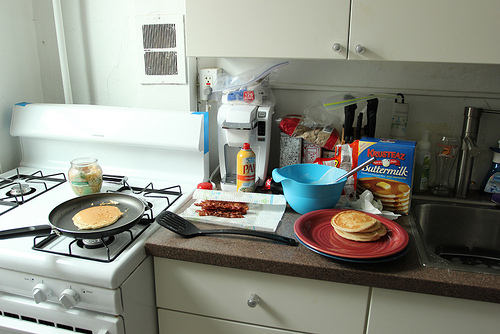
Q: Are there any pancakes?
A: Yes, there are pancakes.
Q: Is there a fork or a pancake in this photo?
A: Yes, there are pancakes.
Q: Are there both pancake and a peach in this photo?
A: No, there are pancakes but no peaches.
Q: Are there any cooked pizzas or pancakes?
A: Yes, there are cooked pancakes.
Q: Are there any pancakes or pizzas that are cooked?
A: Yes, the pancakes are cooked.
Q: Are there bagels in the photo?
A: No, there are no bagels.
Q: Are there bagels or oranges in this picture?
A: No, there are no bagels or oranges.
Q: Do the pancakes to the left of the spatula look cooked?
A: Yes, the pancakes are cooked.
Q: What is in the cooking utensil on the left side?
A: The pancakes are in the skillet.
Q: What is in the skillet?
A: The pancakes are in the skillet.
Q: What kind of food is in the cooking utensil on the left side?
A: The food is pancakes.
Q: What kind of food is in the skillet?
A: The food is pancakes.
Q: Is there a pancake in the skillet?
A: Yes, there are pancakes in the skillet.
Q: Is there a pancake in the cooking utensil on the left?
A: Yes, there are pancakes in the skillet.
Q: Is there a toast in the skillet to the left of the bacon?
A: No, there are pancakes in the skillet.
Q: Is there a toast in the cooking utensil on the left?
A: No, there are pancakes in the skillet.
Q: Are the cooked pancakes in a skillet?
A: Yes, the pancakes are in a skillet.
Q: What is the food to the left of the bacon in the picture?
A: The food is pancakes.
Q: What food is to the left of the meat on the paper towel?
A: The food is pancakes.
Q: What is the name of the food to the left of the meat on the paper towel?
A: The food is pancakes.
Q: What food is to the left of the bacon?
A: The food is pancakes.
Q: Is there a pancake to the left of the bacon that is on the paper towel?
A: Yes, there are pancakes to the left of the bacon.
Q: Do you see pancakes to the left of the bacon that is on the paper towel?
A: Yes, there are pancakes to the left of the bacon.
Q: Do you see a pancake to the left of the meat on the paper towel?
A: Yes, there are pancakes to the left of the bacon.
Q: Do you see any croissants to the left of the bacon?
A: No, there are pancakes to the left of the bacon.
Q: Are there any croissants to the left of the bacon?
A: No, there are pancakes to the left of the bacon.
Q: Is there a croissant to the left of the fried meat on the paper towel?
A: No, there are pancakes to the left of the bacon.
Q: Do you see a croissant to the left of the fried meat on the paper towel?
A: No, there are pancakes to the left of the bacon.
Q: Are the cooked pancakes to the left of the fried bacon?
A: Yes, the pancakes are to the left of the bacon.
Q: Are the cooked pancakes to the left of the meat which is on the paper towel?
A: Yes, the pancakes are to the left of the bacon.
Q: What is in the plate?
A: The pancakes are in the plate.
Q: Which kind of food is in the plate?
A: The food is pancakes.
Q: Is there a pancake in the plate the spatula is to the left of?
A: Yes, there are pancakes in the plate.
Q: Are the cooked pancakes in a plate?
A: Yes, the pancakes are in a plate.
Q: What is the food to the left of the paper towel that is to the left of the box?
A: The food is pancakes.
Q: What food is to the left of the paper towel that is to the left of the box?
A: The food is pancakes.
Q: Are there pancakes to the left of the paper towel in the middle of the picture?
A: Yes, there are pancakes to the left of the paper towel.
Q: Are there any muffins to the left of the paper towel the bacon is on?
A: No, there are pancakes to the left of the paper towel.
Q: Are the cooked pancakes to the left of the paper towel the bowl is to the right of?
A: Yes, the pancakes are to the left of the paper towel.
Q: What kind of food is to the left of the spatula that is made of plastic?
A: The food is pancakes.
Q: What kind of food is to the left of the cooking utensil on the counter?
A: The food is pancakes.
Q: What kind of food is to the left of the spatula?
A: The food is pancakes.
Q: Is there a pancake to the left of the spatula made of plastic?
A: Yes, there are pancakes to the left of the spatula.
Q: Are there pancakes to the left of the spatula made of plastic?
A: Yes, there are pancakes to the left of the spatula.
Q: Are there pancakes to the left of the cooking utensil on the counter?
A: Yes, there are pancakes to the left of the spatula.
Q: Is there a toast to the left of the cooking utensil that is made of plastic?
A: No, there are pancakes to the left of the spatula.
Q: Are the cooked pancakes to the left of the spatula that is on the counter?
A: Yes, the pancakes are to the left of the spatula.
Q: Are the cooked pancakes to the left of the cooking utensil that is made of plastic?
A: Yes, the pancakes are to the left of the spatula.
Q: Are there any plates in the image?
A: Yes, there is a plate.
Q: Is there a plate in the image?
A: Yes, there is a plate.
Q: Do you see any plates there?
A: Yes, there is a plate.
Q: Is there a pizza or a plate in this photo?
A: Yes, there is a plate.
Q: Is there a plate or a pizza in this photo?
A: Yes, there is a plate.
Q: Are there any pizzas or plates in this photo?
A: Yes, there is a plate.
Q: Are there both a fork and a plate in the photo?
A: No, there is a plate but no forks.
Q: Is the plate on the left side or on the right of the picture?
A: The plate is on the right of the image.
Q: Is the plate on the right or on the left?
A: The plate is on the right of the image.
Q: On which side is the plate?
A: The plate is on the right of the image.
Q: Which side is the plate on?
A: The plate is on the right of the image.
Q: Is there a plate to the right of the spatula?
A: Yes, there is a plate to the right of the spatula.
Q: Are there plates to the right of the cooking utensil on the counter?
A: Yes, there is a plate to the right of the spatula.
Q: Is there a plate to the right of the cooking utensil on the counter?
A: Yes, there is a plate to the right of the spatula.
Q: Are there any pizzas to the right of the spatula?
A: No, there is a plate to the right of the spatula.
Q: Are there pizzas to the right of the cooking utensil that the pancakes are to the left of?
A: No, there is a plate to the right of the spatula.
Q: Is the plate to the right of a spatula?
A: Yes, the plate is to the right of a spatula.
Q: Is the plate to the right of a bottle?
A: No, the plate is to the right of a spatula.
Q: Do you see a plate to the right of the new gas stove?
A: Yes, there is a plate to the right of the gas stove.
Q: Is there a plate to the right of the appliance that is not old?
A: Yes, there is a plate to the right of the gas stove.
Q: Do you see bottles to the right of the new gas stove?
A: No, there is a plate to the right of the gas stove.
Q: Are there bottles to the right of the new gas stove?
A: No, there is a plate to the right of the gas stove.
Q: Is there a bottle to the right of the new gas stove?
A: No, there is a plate to the right of the gas stove.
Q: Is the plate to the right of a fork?
A: No, the plate is to the right of the gas stove.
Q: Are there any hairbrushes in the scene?
A: No, there are no hairbrushes.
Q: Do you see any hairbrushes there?
A: No, there are no hairbrushes.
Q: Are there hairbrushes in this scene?
A: No, there are no hairbrushes.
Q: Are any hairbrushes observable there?
A: No, there are no hairbrushes.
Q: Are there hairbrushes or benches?
A: No, there are no hairbrushes or benches.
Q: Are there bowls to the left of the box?
A: Yes, there is a bowl to the left of the box.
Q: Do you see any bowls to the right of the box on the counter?
A: No, the bowl is to the left of the box.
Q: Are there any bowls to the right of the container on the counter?
A: No, the bowl is to the left of the box.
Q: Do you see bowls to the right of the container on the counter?
A: No, the bowl is to the left of the box.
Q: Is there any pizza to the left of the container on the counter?
A: No, there is a bowl to the left of the box.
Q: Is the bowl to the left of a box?
A: Yes, the bowl is to the left of a box.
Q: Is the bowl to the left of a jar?
A: No, the bowl is to the left of a box.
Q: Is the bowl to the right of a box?
A: No, the bowl is to the left of a box.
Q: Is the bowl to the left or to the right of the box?
A: The bowl is to the left of the box.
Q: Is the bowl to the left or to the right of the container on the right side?
A: The bowl is to the left of the box.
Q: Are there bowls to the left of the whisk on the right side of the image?
A: Yes, there is a bowl to the left of the whisk.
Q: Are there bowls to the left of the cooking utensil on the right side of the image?
A: Yes, there is a bowl to the left of the whisk.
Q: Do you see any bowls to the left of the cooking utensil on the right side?
A: Yes, there is a bowl to the left of the whisk.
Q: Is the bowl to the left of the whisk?
A: Yes, the bowl is to the left of the whisk.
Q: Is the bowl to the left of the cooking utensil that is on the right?
A: Yes, the bowl is to the left of the whisk.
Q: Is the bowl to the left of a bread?
A: No, the bowl is to the left of the whisk.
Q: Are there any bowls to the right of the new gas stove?
A: Yes, there is a bowl to the right of the gas stove.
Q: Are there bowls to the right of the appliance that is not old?
A: Yes, there is a bowl to the right of the gas stove.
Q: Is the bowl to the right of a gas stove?
A: Yes, the bowl is to the right of a gas stove.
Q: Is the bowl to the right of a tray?
A: No, the bowl is to the right of a gas stove.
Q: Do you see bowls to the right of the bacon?
A: Yes, there is a bowl to the right of the bacon.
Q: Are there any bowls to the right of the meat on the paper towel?
A: Yes, there is a bowl to the right of the bacon.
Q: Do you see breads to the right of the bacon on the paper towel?
A: No, there is a bowl to the right of the bacon.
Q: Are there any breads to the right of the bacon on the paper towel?
A: No, there is a bowl to the right of the bacon.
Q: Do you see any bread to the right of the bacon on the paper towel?
A: No, there is a bowl to the right of the bacon.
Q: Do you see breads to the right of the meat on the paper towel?
A: No, there is a bowl to the right of the bacon.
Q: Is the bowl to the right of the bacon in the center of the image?
A: Yes, the bowl is to the right of the bacon.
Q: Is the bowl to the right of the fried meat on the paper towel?
A: Yes, the bowl is to the right of the bacon.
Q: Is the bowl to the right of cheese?
A: No, the bowl is to the right of the bacon.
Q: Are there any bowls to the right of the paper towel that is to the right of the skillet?
A: Yes, there is a bowl to the right of the paper towel.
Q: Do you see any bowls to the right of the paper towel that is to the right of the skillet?
A: Yes, there is a bowl to the right of the paper towel.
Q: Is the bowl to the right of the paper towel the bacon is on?
A: Yes, the bowl is to the right of the paper towel.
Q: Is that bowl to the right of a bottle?
A: No, the bowl is to the right of the paper towel.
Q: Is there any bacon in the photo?
A: Yes, there is bacon.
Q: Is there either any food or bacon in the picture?
A: Yes, there is bacon.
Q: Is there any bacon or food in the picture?
A: Yes, there is bacon.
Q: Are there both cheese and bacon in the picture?
A: No, there is bacon but no cheese.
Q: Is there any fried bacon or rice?
A: Yes, there is fried bacon.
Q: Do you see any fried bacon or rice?
A: Yes, there is fried bacon.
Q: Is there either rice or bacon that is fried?
A: Yes, the bacon is fried.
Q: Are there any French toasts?
A: No, there are no French toasts.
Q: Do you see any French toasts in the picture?
A: No, there are no French toasts.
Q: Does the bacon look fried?
A: Yes, the bacon is fried.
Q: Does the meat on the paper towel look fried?
A: Yes, the bacon is fried.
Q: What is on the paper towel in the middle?
A: The bacon is on the paper towel.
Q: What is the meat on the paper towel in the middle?
A: The meat is bacon.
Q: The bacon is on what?
A: The bacon is on the paper towel.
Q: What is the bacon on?
A: The bacon is on the paper towel.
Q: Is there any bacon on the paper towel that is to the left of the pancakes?
A: Yes, there is bacon on the paper towel.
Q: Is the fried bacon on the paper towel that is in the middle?
A: Yes, the bacon is on the paper towel.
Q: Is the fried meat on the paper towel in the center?
A: Yes, the bacon is on the paper towel.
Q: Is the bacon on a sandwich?
A: No, the bacon is on the paper towel.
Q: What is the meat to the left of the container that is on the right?
A: The meat is bacon.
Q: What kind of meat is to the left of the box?
A: The meat is bacon.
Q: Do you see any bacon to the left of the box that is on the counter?
A: Yes, there is bacon to the left of the box.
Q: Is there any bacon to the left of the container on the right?
A: Yes, there is bacon to the left of the box.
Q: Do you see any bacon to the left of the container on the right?
A: Yes, there is bacon to the left of the box.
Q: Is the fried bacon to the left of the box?
A: Yes, the bacon is to the left of the box.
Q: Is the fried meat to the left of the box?
A: Yes, the bacon is to the left of the box.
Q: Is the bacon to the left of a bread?
A: No, the bacon is to the left of the box.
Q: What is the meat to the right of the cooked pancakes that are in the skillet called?
A: The meat is bacon.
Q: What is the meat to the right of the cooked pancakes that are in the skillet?
A: The meat is bacon.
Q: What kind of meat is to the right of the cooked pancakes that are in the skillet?
A: The meat is bacon.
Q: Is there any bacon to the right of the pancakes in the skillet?
A: Yes, there is bacon to the right of the pancakes.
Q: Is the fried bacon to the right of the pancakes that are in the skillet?
A: Yes, the bacon is to the right of the pancakes.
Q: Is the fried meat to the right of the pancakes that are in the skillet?
A: Yes, the bacon is to the right of the pancakes.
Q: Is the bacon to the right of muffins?
A: No, the bacon is to the right of the pancakes.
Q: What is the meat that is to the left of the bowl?
A: The meat is bacon.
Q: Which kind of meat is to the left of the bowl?
A: The meat is bacon.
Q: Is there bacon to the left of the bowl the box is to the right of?
A: Yes, there is bacon to the left of the bowl.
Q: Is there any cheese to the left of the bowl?
A: No, there is bacon to the left of the bowl.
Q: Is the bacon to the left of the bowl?
A: Yes, the bacon is to the left of the bowl.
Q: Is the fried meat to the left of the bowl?
A: Yes, the bacon is to the left of the bowl.